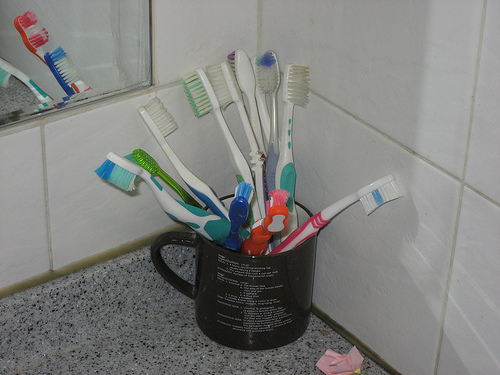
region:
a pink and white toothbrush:
[306, 161, 409, 283]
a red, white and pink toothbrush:
[263, 190, 288, 264]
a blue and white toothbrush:
[221, 180, 253, 280]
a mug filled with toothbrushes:
[91, 150, 437, 367]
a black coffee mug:
[181, 215, 323, 370]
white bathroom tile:
[427, 159, 493, 319]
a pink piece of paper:
[316, 337, 369, 373]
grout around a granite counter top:
[23, 245, 145, 345]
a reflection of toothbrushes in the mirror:
[8, 3, 89, 138]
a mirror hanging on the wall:
[86, 14, 176, 90]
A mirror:
[1, 0, 158, 131]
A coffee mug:
[153, 193, 325, 335]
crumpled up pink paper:
[316, 345, 366, 372]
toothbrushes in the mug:
[84, 39, 411, 263]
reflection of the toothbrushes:
[0, 18, 98, 108]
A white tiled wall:
[3, 2, 498, 374]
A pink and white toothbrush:
[273, 170, 423, 260]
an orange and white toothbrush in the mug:
[245, 192, 292, 259]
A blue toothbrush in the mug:
[221, 185, 251, 258]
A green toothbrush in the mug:
[125, 142, 203, 207]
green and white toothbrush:
[281, 66, 306, 243]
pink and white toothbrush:
[272, 172, 399, 259]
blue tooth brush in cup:
[225, 182, 250, 254]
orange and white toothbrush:
[254, 189, 288, 256]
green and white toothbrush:
[106, 154, 233, 261]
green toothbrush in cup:
[129, 147, 216, 223]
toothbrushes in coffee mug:
[102, 51, 402, 253]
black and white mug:
[156, 226, 320, 346]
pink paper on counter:
[319, 347, 364, 372]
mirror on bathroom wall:
[1, 1, 158, 126]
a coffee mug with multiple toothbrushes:
[90, 28, 425, 348]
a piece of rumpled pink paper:
[320, 341, 365, 373]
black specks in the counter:
[57, 293, 124, 319]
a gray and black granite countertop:
[119, 325, 184, 372]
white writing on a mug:
[219, 255, 296, 340]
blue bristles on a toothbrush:
[372, 191, 385, 208]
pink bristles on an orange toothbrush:
[266, 192, 292, 204]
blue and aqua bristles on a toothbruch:
[99, 168, 133, 190]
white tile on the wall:
[341, 17, 426, 112]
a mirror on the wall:
[38, 11, 151, 93]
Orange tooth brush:
[254, 185, 289, 255]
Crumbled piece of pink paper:
[308, 338, 360, 373]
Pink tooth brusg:
[290, 171, 406, 261]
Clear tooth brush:
[256, 39, 278, 204]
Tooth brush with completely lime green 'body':
[122, 143, 210, 213]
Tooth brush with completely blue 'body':
[224, 176, 247, 255]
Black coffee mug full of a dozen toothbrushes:
[108, 52, 330, 354]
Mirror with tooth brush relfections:
[0, 1, 162, 130]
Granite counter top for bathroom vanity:
[4, 250, 400, 373]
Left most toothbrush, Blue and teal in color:
[94, 149, 228, 246]